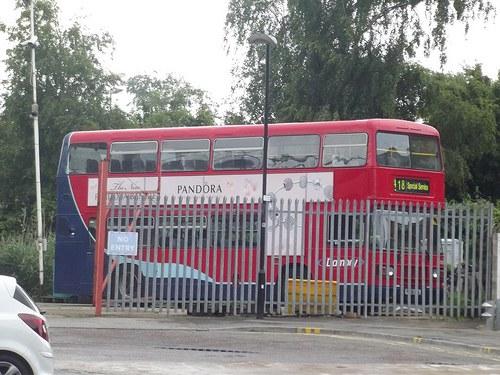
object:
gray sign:
[105, 234, 150, 260]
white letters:
[110, 230, 130, 247]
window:
[320, 128, 359, 167]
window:
[370, 202, 444, 256]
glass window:
[264, 133, 316, 164]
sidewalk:
[264, 319, 494, 350]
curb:
[250, 324, 360, 336]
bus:
[54, 118, 446, 316]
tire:
[275, 262, 314, 302]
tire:
[108, 260, 147, 306]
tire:
[0, 346, 35, 373]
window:
[161, 139, 212, 174]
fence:
[101, 192, 499, 316]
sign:
[85, 172, 335, 204]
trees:
[249, 1, 481, 118]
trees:
[0, 3, 124, 218]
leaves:
[307, 89, 322, 99]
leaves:
[360, 80, 376, 94]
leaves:
[349, 44, 367, 64]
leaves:
[449, 152, 459, 172]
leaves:
[457, 122, 477, 142]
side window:
[65, 140, 110, 176]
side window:
[109, 138, 158, 175]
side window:
[209, 136, 264, 171]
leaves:
[61, 87, 199, 126]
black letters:
[177, 183, 222, 193]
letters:
[400, 180, 440, 193]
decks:
[93, 132, 443, 193]